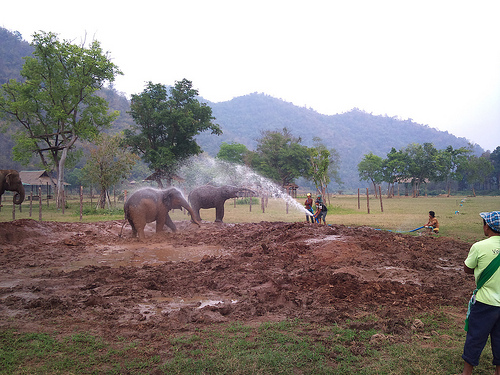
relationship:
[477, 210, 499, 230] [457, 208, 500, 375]
blue hat on guy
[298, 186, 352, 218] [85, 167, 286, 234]
man washing off elephants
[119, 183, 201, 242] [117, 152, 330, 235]
elephant getting a bath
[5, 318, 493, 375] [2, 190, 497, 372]
grass in patches on ground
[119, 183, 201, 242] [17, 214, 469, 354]
elephant in mud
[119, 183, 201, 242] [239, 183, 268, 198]
elephant raise up trunk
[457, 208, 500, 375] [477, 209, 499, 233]
guy wears blue blue hat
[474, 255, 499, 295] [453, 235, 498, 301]
strap over a shirt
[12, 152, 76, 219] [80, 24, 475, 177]
building below mountains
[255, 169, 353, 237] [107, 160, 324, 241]
dudes spraying happy elephant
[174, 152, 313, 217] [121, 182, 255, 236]
water for elephants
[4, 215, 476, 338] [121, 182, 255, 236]
dirt for elephants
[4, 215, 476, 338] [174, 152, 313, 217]
dirt for water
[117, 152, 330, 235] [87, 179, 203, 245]
bath for elephant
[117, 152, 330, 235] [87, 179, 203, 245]
bath a festival for elephant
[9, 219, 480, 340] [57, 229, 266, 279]
muck like a lake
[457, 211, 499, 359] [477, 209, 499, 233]
guy with a blue hat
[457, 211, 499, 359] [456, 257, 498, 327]
guy with a bag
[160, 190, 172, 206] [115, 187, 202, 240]
ear of a elephant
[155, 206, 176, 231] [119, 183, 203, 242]
legs of a elephant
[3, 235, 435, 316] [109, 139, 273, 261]
pit beneath elephants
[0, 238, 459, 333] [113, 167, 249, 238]
mud by elephants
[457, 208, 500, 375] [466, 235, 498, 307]
guy has shirt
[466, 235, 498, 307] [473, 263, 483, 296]
shirt has stripe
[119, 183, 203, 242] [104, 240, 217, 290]
elephant in mud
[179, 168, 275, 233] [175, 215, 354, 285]
elephant in mud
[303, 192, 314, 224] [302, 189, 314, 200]
man wearing hat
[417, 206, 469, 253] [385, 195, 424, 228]
person kneeling on ground